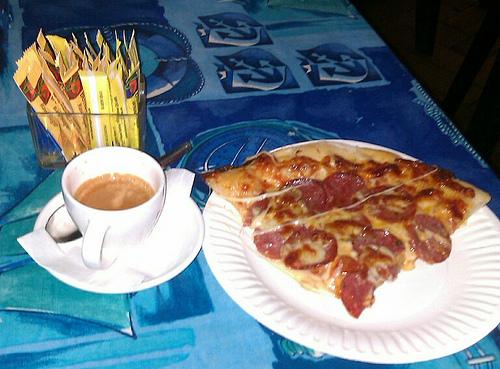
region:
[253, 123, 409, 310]
Pizza on the plate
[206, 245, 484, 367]
White paper plate on the table.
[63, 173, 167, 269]
A cup of coffee on saucer.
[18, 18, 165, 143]
Sugar in the container.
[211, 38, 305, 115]
The tablecloth has anchors on it.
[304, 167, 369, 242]
The pizza has pepperoni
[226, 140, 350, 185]
The crust of the pizza.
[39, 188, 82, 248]
A silver spoon on the saucer.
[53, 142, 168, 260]
A white coffee mug.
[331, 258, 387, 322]
Pepperoni hanging off the pizza.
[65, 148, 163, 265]
cup of coffee in a coffee cup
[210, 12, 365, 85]
three blue anchors on the tablecloth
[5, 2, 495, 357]
blue nautical themed tablecloth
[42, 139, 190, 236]
a metal spoon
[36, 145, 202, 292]
white cut and saucer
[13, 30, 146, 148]
plastic container of sugar packets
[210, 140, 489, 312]
piece of pepperoni pizza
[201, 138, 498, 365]
a white paper plate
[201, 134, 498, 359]
pizza on a paper plate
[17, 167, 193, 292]
white paper napkin under the cup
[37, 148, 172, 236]
a cup with coffee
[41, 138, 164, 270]
a cup with tea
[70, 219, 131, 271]
handle of the cup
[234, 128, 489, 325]
a delicious pizza on plate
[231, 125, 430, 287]
a cool looking pizza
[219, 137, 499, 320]
a hot looking pizza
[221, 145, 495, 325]
a piece of pizza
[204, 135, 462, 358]
a white plate on table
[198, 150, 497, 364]
a round plate with pizza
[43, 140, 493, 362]
a table having two plates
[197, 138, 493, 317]
pepperoni pizza on white plate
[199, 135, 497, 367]
round white paper plate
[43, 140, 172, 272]
hot cocoa in white cup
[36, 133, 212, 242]
spoon on white saucer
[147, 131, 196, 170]
end of spoon hanging off saucer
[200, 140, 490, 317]
melted cheese on top of pepperoni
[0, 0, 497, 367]
blue naval-themed tablecloth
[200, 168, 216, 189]
crust poking out of plate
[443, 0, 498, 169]
dark chair next to table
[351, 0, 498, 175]
hardwood floor in upper right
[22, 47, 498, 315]
a meal for a person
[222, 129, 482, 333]
pizza on a plate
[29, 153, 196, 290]
coffee on a plate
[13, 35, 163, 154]
items in a dish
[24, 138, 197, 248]
a spoon on a saucer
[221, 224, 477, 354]
a white paper plate with pizza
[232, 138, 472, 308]
the pizza is cut into many slices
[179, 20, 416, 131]
the table cloth is blue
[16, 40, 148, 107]
different objects in the dish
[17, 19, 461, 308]
pizza and coffee for people to eat